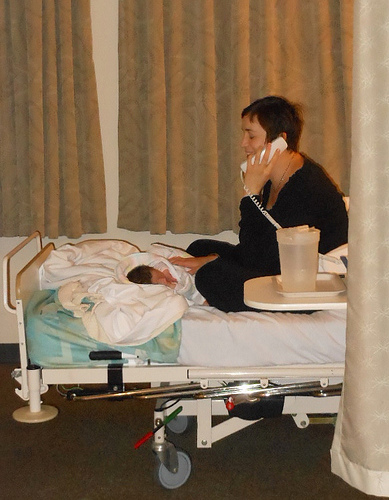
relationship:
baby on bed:
[127, 262, 216, 308] [31, 302, 243, 348]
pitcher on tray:
[274, 226, 315, 287] [270, 270, 341, 301]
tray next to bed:
[270, 270, 341, 301] [19, 229, 362, 484]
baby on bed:
[127, 262, 177, 288] [20, 191, 378, 422]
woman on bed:
[169, 93, 350, 315] [20, 191, 378, 422]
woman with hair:
[169, 93, 350, 315] [235, 92, 306, 155]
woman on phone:
[195, 89, 347, 307] [236, 134, 347, 275]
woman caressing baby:
[195, 89, 347, 307] [119, 240, 200, 307]